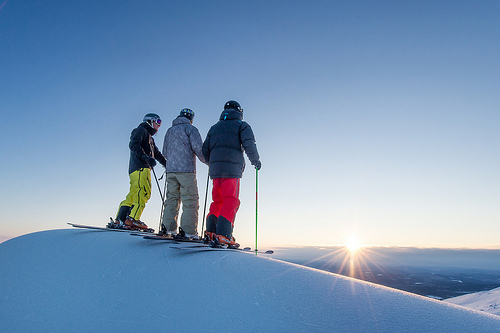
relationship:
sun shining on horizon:
[340, 229, 376, 252] [313, 236, 417, 252]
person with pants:
[200, 100, 262, 250] [210, 178, 243, 230]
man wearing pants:
[107, 113, 166, 230] [114, 165, 150, 212]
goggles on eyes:
[147, 115, 162, 126] [148, 121, 162, 131]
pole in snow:
[246, 162, 262, 248] [239, 242, 290, 272]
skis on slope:
[182, 248, 246, 252] [236, 253, 376, 304]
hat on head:
[221, 98, 245, 114] [215, 99, 246, 123]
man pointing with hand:
[116, 120, 158, 230] [143, 145, 166, 170]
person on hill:
[200, 100, 262, 250] [0, 224, 500, 332]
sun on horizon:
[330, 224, 377, 264] [266, 239, 498, 253]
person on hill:
[200, 100, 262, 250] [2, 224, 496, 331]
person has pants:
[197, 94, 267, 257] [206, 177, 244, 217]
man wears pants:
[107, 113, 166, 230] [117, 172, 153, 215]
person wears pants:
[159, 107, 209, 242] [159, 170, 204, 235]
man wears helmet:
[107, 113, 166, 230] [141, 108, 162, 124]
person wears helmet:
[157, 102, 206, 243] [172, 105, 204, 121]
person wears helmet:
[197, 94, 267, 257] [219, 96, 248, 121]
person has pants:
[200, 100, 262, 250] [204, 174, 244, 224]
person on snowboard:
[200, 100, 262, 250] [132, 227, 208, 243]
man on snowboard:
[107, 113, 166, 230] [64, 218, 158, 236]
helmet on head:
[219, 96, 248, 114] [219, 94, 248, 121]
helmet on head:
[175, 107, 196, 121] [173, 104, 196, 120]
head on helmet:
[139, 107, 164, 134] [139, 109, 160, 127]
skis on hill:
[68, 217, 126, 230] [2, 224, 496, 331]